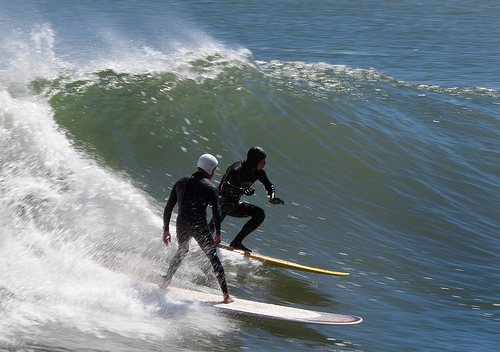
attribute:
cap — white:
[195, 149, 219, 176]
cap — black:
[246, 147, 267, 167]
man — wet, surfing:
[151, 151, 234, 306]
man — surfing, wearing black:
[218, 143, 284, 253]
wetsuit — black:
[216, 170, 276, 251]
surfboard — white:
[147, 284, 361, 332]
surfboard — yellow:
[211, 239, 357, 286]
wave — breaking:
[36, 153, 113, 349]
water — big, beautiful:
[138, 71, 397, 135]